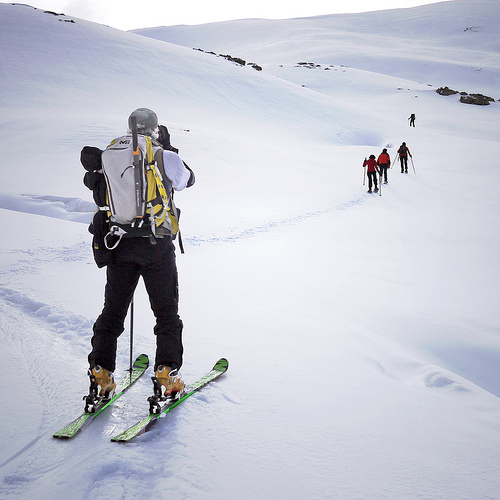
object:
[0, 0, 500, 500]
ground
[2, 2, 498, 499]
snow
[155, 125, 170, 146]
hand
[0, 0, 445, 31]
sky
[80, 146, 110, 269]
packs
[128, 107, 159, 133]
cap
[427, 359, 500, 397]
snow gully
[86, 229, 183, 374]
pants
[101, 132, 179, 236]
backpack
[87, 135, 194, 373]
gear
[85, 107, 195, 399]
skier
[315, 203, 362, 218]
track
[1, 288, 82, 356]
track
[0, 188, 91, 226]
track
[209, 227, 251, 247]
track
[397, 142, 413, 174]
person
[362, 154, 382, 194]
person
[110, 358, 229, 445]
ski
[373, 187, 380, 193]
ski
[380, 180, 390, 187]
ski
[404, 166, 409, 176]
ski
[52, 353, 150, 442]
ski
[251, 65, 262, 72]
rocks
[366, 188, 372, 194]
skis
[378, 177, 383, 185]
skis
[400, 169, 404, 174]
skis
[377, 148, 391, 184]
skier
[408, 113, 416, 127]
skier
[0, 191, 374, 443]
trail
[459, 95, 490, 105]
outcropping